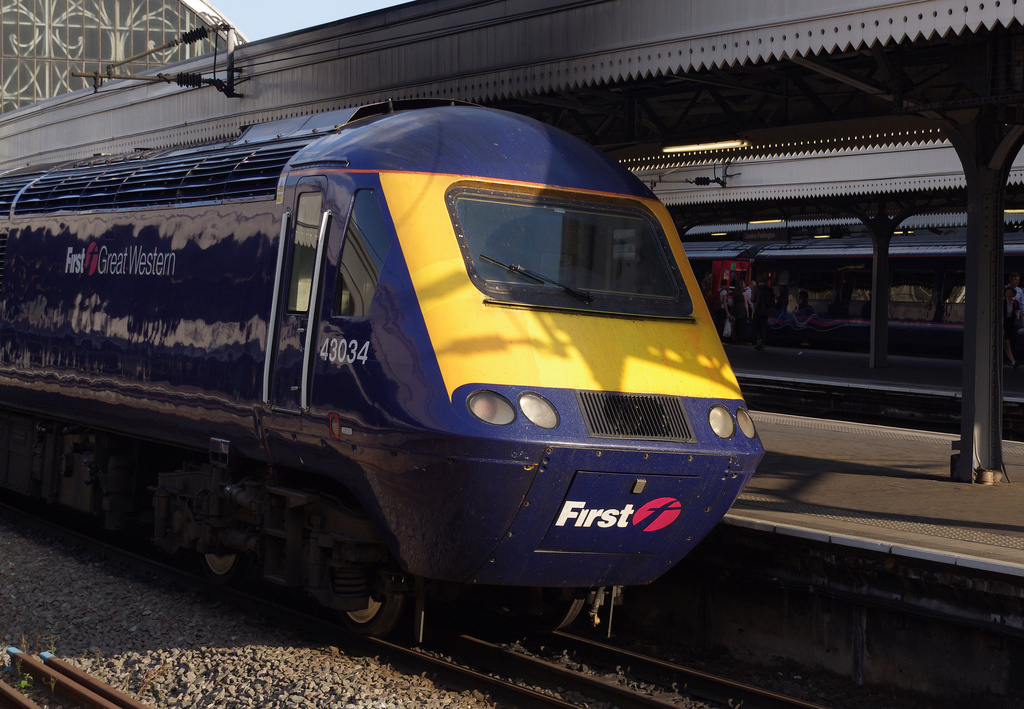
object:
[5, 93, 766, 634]
train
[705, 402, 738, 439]
right headlight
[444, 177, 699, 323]
front window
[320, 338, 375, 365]
number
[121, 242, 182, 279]
western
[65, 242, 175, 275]
great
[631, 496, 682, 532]
emblem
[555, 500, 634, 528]
first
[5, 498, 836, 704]
track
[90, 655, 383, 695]
rock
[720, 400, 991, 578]
sidewalk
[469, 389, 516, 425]
headlight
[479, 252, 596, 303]
windshield wiper